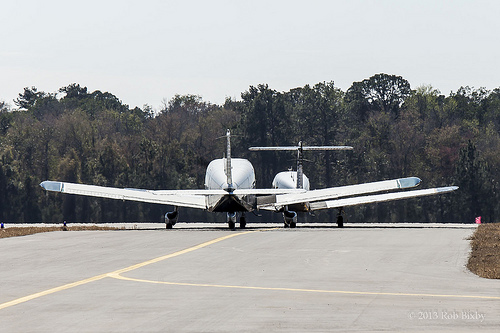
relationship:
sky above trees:
[3, 2, 499, 102] [0, 85, 500, 221]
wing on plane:
[36, 175, 210, 209] [39, 127, 421, 229]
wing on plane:
[305, 185, 459, 208] [39, 127, 421, 229]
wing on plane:
[305, 185, 459, 208] [122, 140, 459, 226]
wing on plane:
[289, 173, 421, 208] [31, 139, 467, 232]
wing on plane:
[36, 175, 210, 209] [31, 139, 467, 232]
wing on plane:
[305, 185, 459, 208] [244, 138, 461, 233]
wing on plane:
[275, 171, 423, 211] [244, 138, 461, 233]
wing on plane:
[184, 185, 291, 199] [39, 127, 421, 229]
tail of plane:
[217, 126, 240, 191] [39, 127, 421, 229]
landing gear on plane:
[162, 207, 182, 228] [39, 127, 421, 229]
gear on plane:
[223, 207, 238, 231] [39, 127, 421, 229]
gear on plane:
[276, 210, 300, 227] [162, 142, 464, 223]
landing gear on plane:
[237, 209, 247, 229] [39, 127, 421, 229]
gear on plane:
[288, 213, 297, 227] [242, 139, 461, 215]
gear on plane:
[225, 213, 236, 231] [117, 126, 289, 246]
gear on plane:
[288, 213, 297, 227] [243, 137, 455, 226]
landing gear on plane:
[152, 210, 358, 230] [39, 127, 421, 229]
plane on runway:
[210, 140, 471, 255] [59, 223, 471, 326]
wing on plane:
[305, 185, 459, 208] [243, 137, 455, 226]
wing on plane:
[232, 171, 423, 211] [39, 127, 421, 229]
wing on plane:
[36, 175, 210, 209] [29, 155, 467, 229]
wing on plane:
[305, 185, 459, 208] [29, 155, 467, 229]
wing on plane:
[275, 171, 423, 211] [242, 139, 461, 215]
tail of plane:
[249, 141, 356, 186] [250, 136, 462, 222]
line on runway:
[2, 227, 258, 312] [2, 227, 498, 330]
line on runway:
[110, 271, 499, 303] [2, 227, 498, 330]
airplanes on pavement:
[24, 125, 460, 234] [0, 221, 500, 329]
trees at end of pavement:
[29, 92, 496, 244] [0, 221, 500, 329]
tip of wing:
[35, 167, 73, 205] [37, 177, 208, 207]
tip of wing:
[395, 172, 423, 191] [248, 172, 420, 207]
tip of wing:
[433, 180, 457, 192] [305, 185, 459, 208]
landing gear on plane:
[334, 215, 345, 227] [244, 138, 461, 233]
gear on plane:
[288, 213, 297, 227] [244, 138, 461, 233]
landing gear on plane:
[239, 216, 247, 228] [39, 127, 421, 229]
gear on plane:
[225, 213, 236, 231] [39, 127, 421, 229]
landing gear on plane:
[163, 211, 175, 228] [39, 127, 421, 229]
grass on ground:
[463, 220, 498, 285] [0, 216, 499, 329]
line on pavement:
[110, 271, 499, 303] [0, 221, 500, 329]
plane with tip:
[39, 127, 421, 229] [392, 176, 424, 199]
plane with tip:
[39, 127, 421, 229] [32, 176, 66, 197]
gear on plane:
[288, 213, 297, 227] [39, 127, 421, 229]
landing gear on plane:
[334, 215, 345, 227] [39, 127, 421, 229]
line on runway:
[2, 227, 241, 312] [2, 227, 498, 330]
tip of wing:
[35, 176, 62, 191] [38, 178, 226, 208]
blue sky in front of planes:
[1, 0, 498, 116] [39, 122, 466, 229]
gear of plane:
[225, 213, 236, 231] [39, 127, 421, 229]